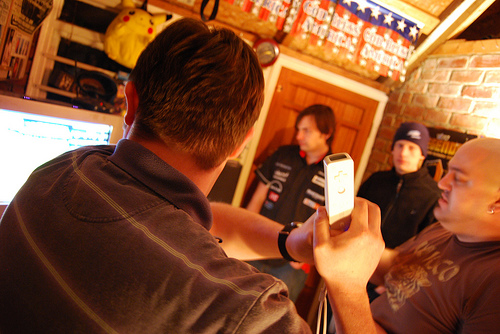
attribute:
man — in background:
[431, 134, 497, 245]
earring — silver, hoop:
[487, 210, 499, 220]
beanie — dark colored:
[389, 118, 431, 155]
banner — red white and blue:
[214, 0, 422, 85]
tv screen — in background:
[2, 99, 137, 207]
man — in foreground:
[2, 17, 383, 332]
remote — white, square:
[320, 151, 357, 230]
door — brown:
[324, 95, 371, 128]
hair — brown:
[287, 100, 338, 156]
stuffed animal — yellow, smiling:
[92, 3, 172, 70]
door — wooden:
[236, 62, 381, 220]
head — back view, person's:
[123, 14, 281, 196]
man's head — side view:
[421, 135, 498, 245]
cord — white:
[313, 274, 340, 331]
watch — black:
[278, 214, 299, 271]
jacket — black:
[358, 160, 448, 243]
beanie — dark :
[360, 108, 450, 203]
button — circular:
[329, 177, 352, 198]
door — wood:
[237, 63, 379, 208]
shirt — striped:
[3, 141, 310, 328]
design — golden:
[397, 249, 424, 300]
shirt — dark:
[382, 225, 499, 325]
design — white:
[408, 125, 418, 141]